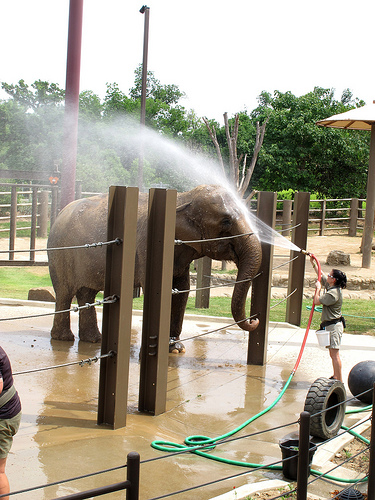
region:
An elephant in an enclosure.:
[20, 161, 358, 426]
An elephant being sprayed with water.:
[35, 117, 322, 378]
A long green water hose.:
[150, 371, 370, 494]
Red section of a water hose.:
[292, 248, 322, 372]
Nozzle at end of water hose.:
[294, 243, 315, 260]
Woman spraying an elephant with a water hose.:
[27, 160, 354, 431]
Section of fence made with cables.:
[4, 188, 306, 408]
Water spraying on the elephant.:
[44, 107, 299, 257]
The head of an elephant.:
[171, 180, 255, 258]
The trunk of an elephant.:
[222, 236, 262, 337]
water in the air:
[123, 136, 178, 162]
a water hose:
[155, 439, 183, 463]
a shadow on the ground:
[63, 448, 111, 467]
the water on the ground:
[193, 385, 239, 417]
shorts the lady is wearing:
[329, 324, 342, 344]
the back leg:
[53, 282, 78, 348]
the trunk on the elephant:
[234, 288, 257, 332]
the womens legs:
[329, 350, 345, 378]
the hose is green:
[188, 433, 212, 451]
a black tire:
[306, 387, 330, 407]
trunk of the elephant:
[236, 260, 257, 328]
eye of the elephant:
[218, 217, 232, 224]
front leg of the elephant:
[170, 276, 190, 352]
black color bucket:
[282, 441, 298, 479]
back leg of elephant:
[51, 287, 73, 341]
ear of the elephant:
[175, 202, 199, 250]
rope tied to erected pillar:
[35, 357, 105, 370]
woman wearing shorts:
[327, 324, 343, 349]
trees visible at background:
[266, 105, 311, 181]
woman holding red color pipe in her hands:
[310, 252, 320, 287]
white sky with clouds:
[192, 31, 374, 74]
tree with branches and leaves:
[272, 133, 334, 173]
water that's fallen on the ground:
[44, 430, 107, 465]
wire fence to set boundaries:
[151, 455, 179, 459]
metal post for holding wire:
[103, 269, 126, 427]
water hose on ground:
[157, 433, 214, 456]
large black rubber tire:
[306, 375, 345, 435]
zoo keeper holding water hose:
[304, 253, 346, 381]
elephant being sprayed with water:
[46, 186, 259, 357]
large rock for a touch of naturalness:
[327, 247, 350, 264]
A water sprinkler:
[300, 249, 304, 253]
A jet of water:
[287, 243, 292, 247]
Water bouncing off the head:
[216, 178, 223, 184]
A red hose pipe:
[300, 350, 302, 354]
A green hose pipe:
[240, 424, 242, 427]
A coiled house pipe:
[188, 436, 203, 443]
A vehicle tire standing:
[310, 386, 324, 407]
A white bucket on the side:
[319, 332, 327, 343]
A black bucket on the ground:
[285, 466, 296, 477]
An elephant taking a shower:
[187, 190, 233, 233]